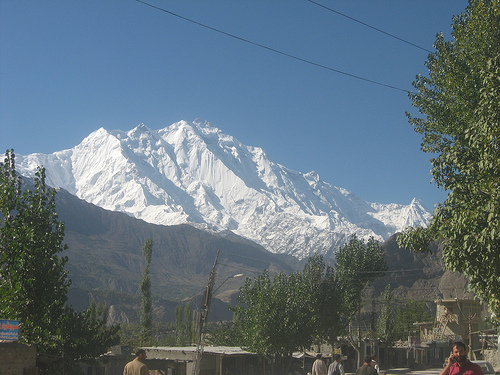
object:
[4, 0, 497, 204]
sky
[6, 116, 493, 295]
mountain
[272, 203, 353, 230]
snow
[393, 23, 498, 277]
tree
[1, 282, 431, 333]
mountain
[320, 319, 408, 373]
buildings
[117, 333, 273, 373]
building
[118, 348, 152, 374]
man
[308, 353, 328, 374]
man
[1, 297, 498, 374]
village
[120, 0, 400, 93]
wire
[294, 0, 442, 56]
wire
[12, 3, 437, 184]
air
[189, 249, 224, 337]
trees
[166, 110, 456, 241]
mountain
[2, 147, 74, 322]
tree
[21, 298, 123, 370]
tree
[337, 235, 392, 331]
tree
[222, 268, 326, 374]
tree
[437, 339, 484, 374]
man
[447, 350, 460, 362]
phone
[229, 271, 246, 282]
light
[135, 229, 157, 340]
tree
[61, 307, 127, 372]
tree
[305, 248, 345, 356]
tree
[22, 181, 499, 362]
mountain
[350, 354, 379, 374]
man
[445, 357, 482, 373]
shirt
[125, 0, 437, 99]
lines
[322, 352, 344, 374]
people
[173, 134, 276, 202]
snow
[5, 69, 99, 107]
cloud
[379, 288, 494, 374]
building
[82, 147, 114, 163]
snow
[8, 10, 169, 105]
sky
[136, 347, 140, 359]
hair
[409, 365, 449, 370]
street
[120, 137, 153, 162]
snow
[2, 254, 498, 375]
town